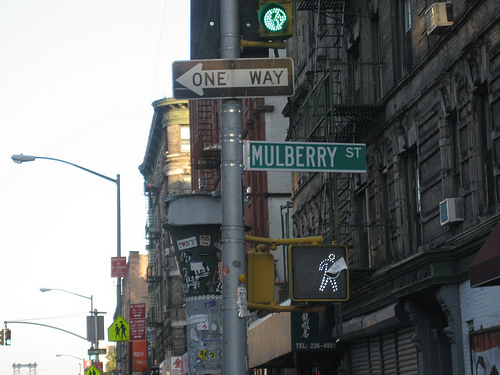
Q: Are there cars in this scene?
A: No, there are no cars.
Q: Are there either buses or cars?
A: No, there are no cars or buses.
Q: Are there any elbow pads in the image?
A: No, there are no elbow pads.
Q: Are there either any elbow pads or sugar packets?
A: No, there are no elbow pads or sugar packets.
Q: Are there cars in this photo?
A: No, there are no cars.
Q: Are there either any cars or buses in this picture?
A: No, there are no cars or buses.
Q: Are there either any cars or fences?
A: No, there are no cars or fences.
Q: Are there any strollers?
A: No, there are no strollers.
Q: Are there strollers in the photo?
A: No, there are no strollers.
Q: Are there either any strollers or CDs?
A: No, there are no strollers or cds.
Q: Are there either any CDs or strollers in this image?
A: No, there are no strollers or cds.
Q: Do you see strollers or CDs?
A: No, there are no strollers or cds.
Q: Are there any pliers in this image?
A: No, there are no pliers.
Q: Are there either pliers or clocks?
A: No, there are no pliers or clocks.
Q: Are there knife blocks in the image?
A: No, there are no knife blocks.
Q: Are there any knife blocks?
A: No, there are no knife blocks.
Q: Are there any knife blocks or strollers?
A: No, there are no knife blocks or strollers.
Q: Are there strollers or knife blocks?
A: No, there are no knife blocks or strollers.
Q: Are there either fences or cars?
A: No, there are no fences or cars.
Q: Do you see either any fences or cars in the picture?
A: No, there are no fences or cars.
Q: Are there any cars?
A: No, there are no cars.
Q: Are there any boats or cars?
A: No, there are no cars or boats.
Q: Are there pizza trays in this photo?
A: No, there are no pizza trays.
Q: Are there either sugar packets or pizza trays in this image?
A: No, there are no pizza trays or sugar packets.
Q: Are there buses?
A: No, there are no buses.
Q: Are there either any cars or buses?
A: No, there are no buses or cars.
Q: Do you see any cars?
A: No, there are no cars.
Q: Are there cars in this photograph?
A: No, there are no cars.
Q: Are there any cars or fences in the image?
A: No, there are no cars or fences.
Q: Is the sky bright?
A: Yes, the sky is bright.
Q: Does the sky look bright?
A: Yes, the sky is bright.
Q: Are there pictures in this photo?
A: No, there are no pictures.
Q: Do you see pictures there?
A: No, there are no pictures.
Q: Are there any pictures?
A: No, there are no pictures.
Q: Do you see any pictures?
A: No, there are no pictures.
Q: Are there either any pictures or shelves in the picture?
A: No, there are no pictures or shelves.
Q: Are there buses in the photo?
A: No, there are no buses.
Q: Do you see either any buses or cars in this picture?
A: No, there are no buses or cars.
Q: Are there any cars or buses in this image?
A: No, there are no buses or cars.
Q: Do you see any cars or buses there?
A: No, there are no buses or cars.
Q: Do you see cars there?
A: No, there are no cars.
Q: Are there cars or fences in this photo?
A: No, there are no cars or fences.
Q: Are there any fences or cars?
A: No, there are no cars or fences.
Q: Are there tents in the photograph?
A: No, there are no tents.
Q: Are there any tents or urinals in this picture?
A: No, there are no tents or urinals.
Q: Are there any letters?
A: Yes, there are letters.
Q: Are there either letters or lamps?
A: Yes, there are letters.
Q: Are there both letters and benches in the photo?
A: No, there are letters but no benches.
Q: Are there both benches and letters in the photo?
A: No, there are letters but no benches.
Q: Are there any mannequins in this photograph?
A: No, there are no mannequins.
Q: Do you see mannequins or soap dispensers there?
A: No, there are no mannequins or soap dispensers.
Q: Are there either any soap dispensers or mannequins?
A: No, there are no mannequins or soap dispensers.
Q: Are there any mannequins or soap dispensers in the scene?
A: No, there are no mannequins or soap dispensers.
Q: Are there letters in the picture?
A: Yes, there are letters.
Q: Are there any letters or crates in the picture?
A: Yes, there are letters.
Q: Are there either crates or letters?
A: Yes, there are letters.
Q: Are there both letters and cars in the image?
A: No, there are letters but no cars.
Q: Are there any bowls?
A: No, there are no bowls.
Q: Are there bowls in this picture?
A: No, there are no bowls.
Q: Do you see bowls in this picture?
A: No, there are no bowls.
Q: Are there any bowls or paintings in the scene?
A: No, there are no bowls or paintings.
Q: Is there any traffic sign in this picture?
A: Yes, there is a traffic sign.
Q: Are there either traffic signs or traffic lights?
A: Yes, there is a traffic sign.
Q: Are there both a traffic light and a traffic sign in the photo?
A: Yes, there are both a traffic sign and a traffic light.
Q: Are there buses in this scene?
A: No, there are no buses.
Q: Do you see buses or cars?
A: No, there are no buses or cars.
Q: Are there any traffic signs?
A: Yes, there is a traffic sign.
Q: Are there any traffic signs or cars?
A: Yes, there is a traffic sign.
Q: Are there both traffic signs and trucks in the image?
A: No, there is a traffic sign but no trucks.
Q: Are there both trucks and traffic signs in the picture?
A: No, there is a traffic sign but no trucks.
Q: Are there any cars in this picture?
A: No, there are no cars.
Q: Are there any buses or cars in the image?
A: No, there are no cars or buses.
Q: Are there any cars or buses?
A: No, there are no cars or buses.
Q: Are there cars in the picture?
A: No, there are no cars.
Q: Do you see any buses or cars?
A: No, there are no cars or buses.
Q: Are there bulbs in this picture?
A: No, there are no bulbs.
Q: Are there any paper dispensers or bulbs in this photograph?
A: No, there are no bulbs or paper dispensers.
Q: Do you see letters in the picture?
A: Yes, there are letters.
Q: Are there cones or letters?
A: Yes, there are letters.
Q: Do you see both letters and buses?
A: No, there are letters but no buses.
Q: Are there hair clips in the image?
A: No, there are no hair clips.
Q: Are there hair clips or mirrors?
A: No, there are no hair clips or mirrors.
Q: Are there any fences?
A: No, there are no fences.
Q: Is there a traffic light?
A: Yes, there is a traffic light.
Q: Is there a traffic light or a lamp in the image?
A: Yes, there is a traffic light.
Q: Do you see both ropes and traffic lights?
A: No, there is a traffic light but no ropes.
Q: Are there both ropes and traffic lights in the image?
A: No, there is a traffic light but no ropes.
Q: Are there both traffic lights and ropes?
A: No, there is a traffic light but no ropes.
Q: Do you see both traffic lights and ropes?
A: No, there is a traffic light but no ropes.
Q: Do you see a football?
A: No, there are no footballs.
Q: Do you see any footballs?
A: No, there are no footballs.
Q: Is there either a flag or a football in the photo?
A: No, there are no footballs or flags.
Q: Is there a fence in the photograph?
A: No, there are no fences.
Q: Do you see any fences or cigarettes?
A: No, there are no fences or cigarettes.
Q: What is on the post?
A: The sticker is on the post.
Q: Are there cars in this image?
A: No, there are no cars.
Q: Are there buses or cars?
A: No, there are no cars or buses.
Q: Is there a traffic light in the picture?
A: Yes, there is a traffic light.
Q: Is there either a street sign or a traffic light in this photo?
A: Yes, there is a traffic light.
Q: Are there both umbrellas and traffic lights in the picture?
A: No, there is a traffic light but no umbrellas.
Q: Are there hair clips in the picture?
A: No, there are no hair clips.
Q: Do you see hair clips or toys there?
A: No, there are no hair clips or toys.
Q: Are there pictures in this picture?
A: No, there are no pictures.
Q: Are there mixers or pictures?
A: No, there are no pictures or mixers.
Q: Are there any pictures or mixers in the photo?
A: No, there are no pictures or mixers.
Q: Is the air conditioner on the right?
A: Yes, the air conditioner is on the right of the image.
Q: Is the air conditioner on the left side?
A: No, the air conditioner is on the right of the image.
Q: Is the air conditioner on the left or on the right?
A: The air conditioner is on the right of the image.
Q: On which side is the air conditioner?
A: The air conditioner is on the right of the image.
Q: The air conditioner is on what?
A: The air conditioner is on the wall.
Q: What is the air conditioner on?
A: The air conditioner is on the wall.